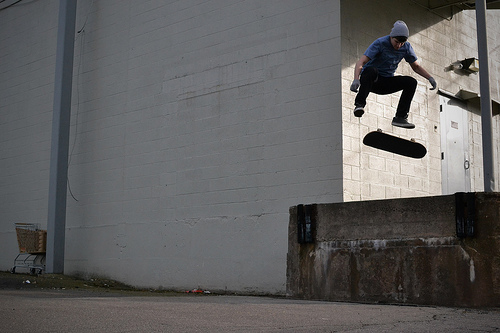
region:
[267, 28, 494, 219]
a man on a skateboard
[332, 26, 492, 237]
a man that is skateboarding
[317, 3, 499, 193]
a man skateboarding outside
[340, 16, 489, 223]
a man doing a stutn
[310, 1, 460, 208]
a man doing a trick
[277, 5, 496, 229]
a man doing a skateboard trick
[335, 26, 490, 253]
a man doing a skateboard stunt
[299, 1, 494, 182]
a man wearing a beanie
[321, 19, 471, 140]
a man wearing a shirt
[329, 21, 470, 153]
a man wearing pants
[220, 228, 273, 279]
Part of a brick wall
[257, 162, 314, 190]
Part of a brick wall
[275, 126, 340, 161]
Part of a brick wall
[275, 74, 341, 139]
Part of a brick wall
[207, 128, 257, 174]
Part of a brick wall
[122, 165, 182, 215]
Part of a brick wall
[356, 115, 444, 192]
Black skateboard in the air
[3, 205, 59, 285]
Part of a shopping cart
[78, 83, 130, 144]
Part of a brick wall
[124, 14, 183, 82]
Part of a brick wall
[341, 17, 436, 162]
the person is skateboarding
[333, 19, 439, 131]
the person is in the air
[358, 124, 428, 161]
the board is upside down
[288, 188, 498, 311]
concrete truck docking bay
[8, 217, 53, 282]
shopping cart with brown plastic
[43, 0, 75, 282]
large grey pole against wall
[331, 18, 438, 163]
skater is hitting the gap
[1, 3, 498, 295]
wall is made of white bricks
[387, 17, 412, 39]
hat is grey stocking cap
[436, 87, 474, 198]
door is solid gray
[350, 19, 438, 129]
the boy in mid air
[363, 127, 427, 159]
the skateboard in mid air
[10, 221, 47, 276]
the shopping cart near the building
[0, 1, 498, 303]
the building made of cement blocks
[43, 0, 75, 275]
the pole next to the building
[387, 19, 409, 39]
the beanie on the boy's head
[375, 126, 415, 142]
the wheels under the skateboard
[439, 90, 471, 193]
the door to the building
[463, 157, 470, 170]
the handle on the door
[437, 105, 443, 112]
the hinge on the door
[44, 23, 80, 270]
the pole is gray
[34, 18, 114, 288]
the pole is gray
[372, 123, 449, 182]
the skateboard is black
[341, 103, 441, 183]
the skateboard is black